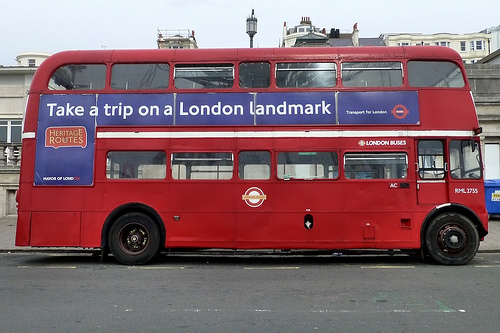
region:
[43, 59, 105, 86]
window on passenger bus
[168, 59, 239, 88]
window on passenger bus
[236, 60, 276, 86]
window on passenger bus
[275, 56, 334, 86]
window on passenger bus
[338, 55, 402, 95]
window on passenger bus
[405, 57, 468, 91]
window on passenger bus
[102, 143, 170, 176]
window on passenger bus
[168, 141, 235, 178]
window on passenger bus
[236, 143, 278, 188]
window on passenger bus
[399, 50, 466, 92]
window of a bus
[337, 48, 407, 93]
window of a bus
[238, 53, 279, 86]
window of a bus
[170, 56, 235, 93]
window of a bus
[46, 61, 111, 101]
window of a bus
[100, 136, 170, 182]
window of a bus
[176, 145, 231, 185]
window of a bus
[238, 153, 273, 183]
window of a bus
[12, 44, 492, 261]
A double decker bus in front of building.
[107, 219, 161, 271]
The tire on the bus.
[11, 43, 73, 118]
Building behind the bus.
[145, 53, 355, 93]
Windows on the bus.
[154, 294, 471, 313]
White marks on the street.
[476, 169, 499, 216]
Blue garbage bin by the building.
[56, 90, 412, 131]
advertisement on the bus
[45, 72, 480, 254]
two tiered bus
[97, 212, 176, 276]
wheels on bus are black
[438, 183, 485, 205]
serial number on bus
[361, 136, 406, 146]
name of company on bus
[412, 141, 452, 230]
door to get on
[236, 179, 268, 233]
emblem in middle of bus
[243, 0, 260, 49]
light post on back of bus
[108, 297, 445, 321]
white markings in the road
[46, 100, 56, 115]
white letter on bus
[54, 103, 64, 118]
white letter on bus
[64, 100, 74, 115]
white letter on bus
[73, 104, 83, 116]
white letter on bus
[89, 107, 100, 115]
white letter on bus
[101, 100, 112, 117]
white letter on bus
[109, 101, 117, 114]
white letter on bus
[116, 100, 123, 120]
white letter on bus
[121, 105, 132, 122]
white letter on bus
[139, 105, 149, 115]
white letter on bus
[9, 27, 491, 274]
a red two level bus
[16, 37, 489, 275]
a bus parked next to a curb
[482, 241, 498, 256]
a concrete curb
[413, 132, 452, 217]
a doorway on a bus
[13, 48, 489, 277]
The bus is red.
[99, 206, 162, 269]
The tire is round and black.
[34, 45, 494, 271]
The bus is double decker.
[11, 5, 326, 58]
The sky is clear and blue.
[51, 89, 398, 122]
A blue sign on the bus.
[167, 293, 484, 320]
A faded white line on the road.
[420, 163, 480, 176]
Steering wheel in the bus.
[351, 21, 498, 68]
A building behind the bus.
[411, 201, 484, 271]
Front tire of the bus.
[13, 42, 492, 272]
red double decker bus on street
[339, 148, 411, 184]
window on side of red double decker bus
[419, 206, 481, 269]
front black wheel on red bus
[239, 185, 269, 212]
white circular logo on side of bus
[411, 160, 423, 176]
silver handle on door on side of bus